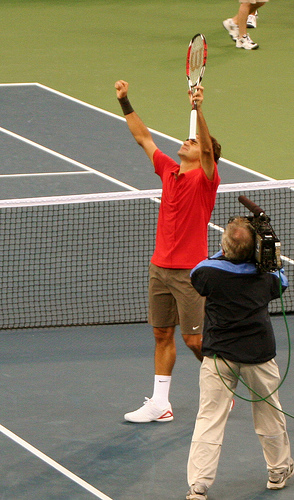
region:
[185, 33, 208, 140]
this is a tennis racket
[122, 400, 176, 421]
white shoes for playing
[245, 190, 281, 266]
this is a video camera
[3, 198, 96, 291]
this is part of a net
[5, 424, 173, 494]
section of the tennis pitch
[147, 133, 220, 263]
he is wearing an orange tshirt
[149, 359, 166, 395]
he is wearing socks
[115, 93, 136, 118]
he is wearing a wrist band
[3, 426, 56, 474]
white line drawn on the tennis pitch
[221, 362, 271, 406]
wires connecting to the video camera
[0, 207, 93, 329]
Black net used in tennis matches.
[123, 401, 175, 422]
One white sneaker with red design.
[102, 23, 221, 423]
A male tennis player.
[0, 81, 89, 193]
The grey flooring with white lines.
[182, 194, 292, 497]
The camera man with khaki pants.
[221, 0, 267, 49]
The white sneakers of a person.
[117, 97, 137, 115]
The man's brown wrist band.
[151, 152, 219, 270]
The man's red shirt.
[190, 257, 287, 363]
The man's black and blue shirt.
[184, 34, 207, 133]
The tennis racket with a "W".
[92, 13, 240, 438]
Tennis player celebrating a victory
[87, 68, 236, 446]
Tennis player wears red shirt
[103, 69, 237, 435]
Tennis player wears white tennis shoes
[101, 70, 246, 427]
Tennis player wears brown short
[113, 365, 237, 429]
Tennis player wears white socks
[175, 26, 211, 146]
Tennis racket is white, red and black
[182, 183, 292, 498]
Cameraman filming a tennis player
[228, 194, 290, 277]
Camera pointing tennis player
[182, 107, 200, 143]
Handle of racket is white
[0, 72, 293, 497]
Tennis field is gray with white lines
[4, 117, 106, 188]
Part of a tennis court.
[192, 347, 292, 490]
A pair of beige pants.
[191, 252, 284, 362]
A black jacket with blue stripe.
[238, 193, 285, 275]
A camera to record the action.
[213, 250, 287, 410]
Green cable attached to camera.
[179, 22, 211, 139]
An orange, black and white tennis racquet.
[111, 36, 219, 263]
A tennis player with his arms in air.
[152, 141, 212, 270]
An orange shirt.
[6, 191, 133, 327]
Part of the tennis net.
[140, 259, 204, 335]
A pair of shorts.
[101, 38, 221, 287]
a player holding a tennis racquet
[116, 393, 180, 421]
a white and red tennis shoe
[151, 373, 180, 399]
white crew sock with logo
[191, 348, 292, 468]
a person in tan cargo pants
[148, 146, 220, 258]
a person in a red shirt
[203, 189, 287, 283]
a person with a video camera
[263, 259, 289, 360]
green wire connecting to a video camera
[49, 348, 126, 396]
a grey tennis court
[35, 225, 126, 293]
black netting of a tennis net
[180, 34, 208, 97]
a black, red and white tennis racquet